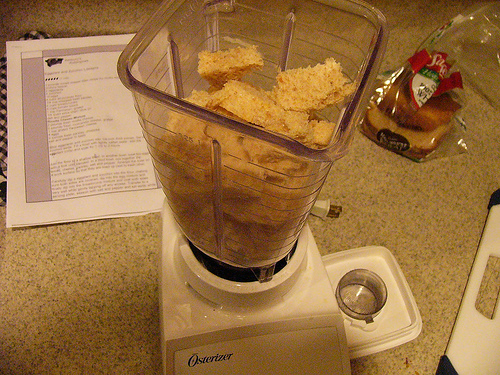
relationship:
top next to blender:
[324, 247, 423, 361] [157, 196, 353, 373]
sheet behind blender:
[4, 35, 156, 232] [157, 196, 353, 373]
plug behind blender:
[310, 196, 344, 221] [157, 196, 353, 373]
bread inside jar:
[152, 50, 354, 268] [115, 0, 387, 286]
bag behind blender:
[361, 0, 498, 162] [157, 196, 353, 373]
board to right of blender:
[437, 187, 500, 373] [157, 196, 353, 373]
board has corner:
[437, 187, 500, 373] [487, 186, 499, 210]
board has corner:
[437, 187, 500, 373] [432, 356, 457, 374]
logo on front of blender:
[188, 353, 234, 368] [157, 196, 353, 373]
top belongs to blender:
[324, 247, 423, 361] [157, 196, 353, 373]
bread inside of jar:
[152, 50, 354, 268] [115, 0, 387, 286]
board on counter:
[437, 187, 500, 373] [2, 0, 499, 374]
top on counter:
[324, 247, 423, 361] [2, 0, 499, 374]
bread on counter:
[360, 62, 461, 161] [2, 0, 499, 374]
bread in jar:
[152, 50, 354, 268] [115, 0, 387, 286]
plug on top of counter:
[310, 196, 344, 221] [2, 0, 499, 374]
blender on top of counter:
[157, 196, 353, 373] [2, 0, 499, 374]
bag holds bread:
[361, 0, 498, 162] [360, 62, 461, 161]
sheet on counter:
[4, 35, 156, 232] [2, 0, 499, 374]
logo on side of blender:
[188, 353, 234, 368] [157, 196, 353, 373]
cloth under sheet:
[0, 32, 53, 203] [4, 35, 156, 232]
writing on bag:
[413, 53, 457, 103] [361, 0, 498, 162]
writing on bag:
[377, 129, 410, 152] [361, 0, 498, 162]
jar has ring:
[115, 0, 387, 286] [184, 240, 306, 280]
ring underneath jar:
[184, 240, 306, 280] [115, 0, 387, 286]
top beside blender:
[324, 247, 423, 361] [157, 196, 353, 373]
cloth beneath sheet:
[0, 32, 53, 203] [4, 35, 156, 232]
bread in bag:
[360, 62, 461, 161] [361, 0, 498, 162]